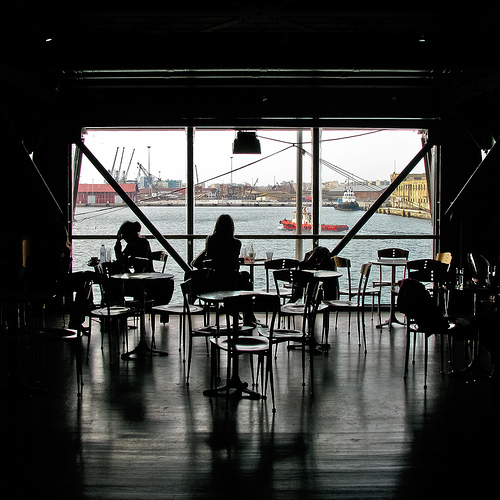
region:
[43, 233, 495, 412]
room with table and chairs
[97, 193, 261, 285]
two women are sitting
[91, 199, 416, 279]
water can be seen out of the window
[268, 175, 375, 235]
two boats are on the water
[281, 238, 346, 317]
this person has their head down on the table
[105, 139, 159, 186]
a few cranes are in the background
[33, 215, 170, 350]
two women are sitting at the same table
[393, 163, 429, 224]
a building can be seen to the right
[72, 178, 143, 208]
a smaller red building is to the left of the water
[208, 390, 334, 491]
shadows from the table and chairs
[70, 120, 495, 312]
view of the harbor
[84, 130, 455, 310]
view of loading docks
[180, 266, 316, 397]
table and chair set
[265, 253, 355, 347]
table and chair set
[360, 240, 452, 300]
table and chair set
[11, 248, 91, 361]
table and chair set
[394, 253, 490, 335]
table and chair set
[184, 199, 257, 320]
woman sitting at table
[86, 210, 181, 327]
woman sitting at table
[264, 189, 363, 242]
boat in the water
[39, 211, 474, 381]
seating area by water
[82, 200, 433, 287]
water with boat in it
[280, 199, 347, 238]
boat in the water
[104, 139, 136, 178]
cranes near the water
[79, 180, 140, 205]
red building near water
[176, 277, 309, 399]
table with chairs around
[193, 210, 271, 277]
person alone at table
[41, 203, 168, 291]
women at table together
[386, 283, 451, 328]
item on chair at table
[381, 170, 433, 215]
tan building near water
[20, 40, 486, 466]
window separating restaurant from seaside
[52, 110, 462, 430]
people, tables and chairs silhouetted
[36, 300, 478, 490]
black floor reflecting light from outside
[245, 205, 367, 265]
red tugboat in calm gray water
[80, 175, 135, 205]
low red building with grey doorways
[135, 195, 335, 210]
low horizontal partition on top of the water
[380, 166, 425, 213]
yellow building along the waterfront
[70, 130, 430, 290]
slanted poles and suppors against elevated metal wires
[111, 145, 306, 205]
various structures and objects across from water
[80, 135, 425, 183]
bright gray sky over seaport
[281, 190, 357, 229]
Boats in the water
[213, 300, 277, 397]
A chair at the table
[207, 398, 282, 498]
A shadow on the floor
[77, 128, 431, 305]
A large window in the room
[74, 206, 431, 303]
Water beneath the boats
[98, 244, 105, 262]
A plastic bottle on the table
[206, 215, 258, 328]
A woman sitting in the chair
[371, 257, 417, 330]
A table by the window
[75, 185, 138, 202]
A red building by the water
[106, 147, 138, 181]
Cranes behind the red building